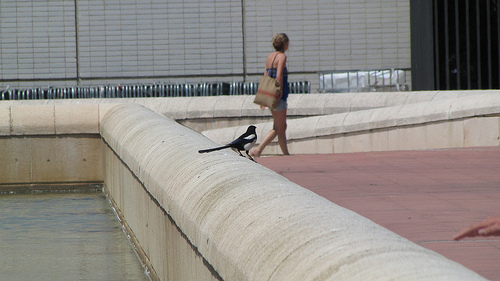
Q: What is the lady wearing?
A: Clothes.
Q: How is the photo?
A: Clear.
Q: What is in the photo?
A: A bird.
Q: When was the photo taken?
A: Daytime.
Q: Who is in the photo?
A: A lady.